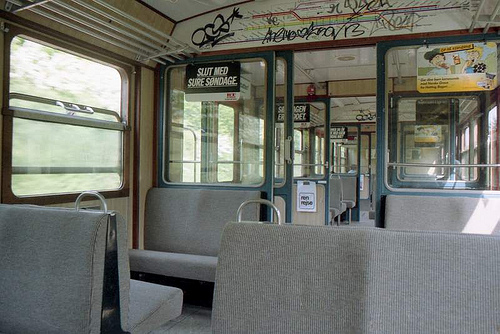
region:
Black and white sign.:
[180, 57, 241, 93]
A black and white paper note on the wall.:
[297, 179, 316, 214]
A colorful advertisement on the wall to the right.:
[414, 39, 499, 93]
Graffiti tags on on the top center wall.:
[186, 2, 429, 46]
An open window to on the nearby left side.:
[4, 35, 133, 194]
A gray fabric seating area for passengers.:
[124, 188, 260, 270]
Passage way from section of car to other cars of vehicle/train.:
[281, 44, 381, 223]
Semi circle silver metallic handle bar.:
[232, 199, 284, 230]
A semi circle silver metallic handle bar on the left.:
[71, 189, 111, 211]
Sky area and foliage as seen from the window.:
[6, 40, 127, 102]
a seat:
[149, 188, 216, 270]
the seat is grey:
[157, 190, 209, 271]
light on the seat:
[462, 201, 499, 231]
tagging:
[189, 20, 261, 50]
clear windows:
[7, 45, 136, 188]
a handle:
[244, 194, 281, 217]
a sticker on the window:
[408, 48, 498, 93]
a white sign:
[296, 183, 317, 208]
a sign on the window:
[185, 65, 245, 92]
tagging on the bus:
[262, 22, 367, 49]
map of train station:
[169, 1, 475, 48]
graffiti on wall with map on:
[183, 0, 249, 55]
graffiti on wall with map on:
[261, 22, 366, 38]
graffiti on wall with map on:
[369, 11, 414, 36]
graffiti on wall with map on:
[329, 0, 409, 18]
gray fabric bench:
[134, 182, 263, 269]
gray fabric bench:
[2, 200, 112, 332]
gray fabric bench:
[101, 205, 188, 331]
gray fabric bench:
[383, 189, 498, 231]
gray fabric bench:
[212, 212, 498, 332]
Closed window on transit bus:
[5, 106, 135, 201]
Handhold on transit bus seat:
[229, 200, 297, 228]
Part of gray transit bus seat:
[25, 245, 71, 290]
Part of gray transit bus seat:
[242, 271, 328, 310]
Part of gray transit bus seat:
[164, 207, 219, 252]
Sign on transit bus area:
[296, 178, 321, 211]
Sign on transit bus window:
[181, 61, 251, 96]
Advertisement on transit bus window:
[416, 40, 499, 90]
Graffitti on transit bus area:
[183, 10, 255, 45]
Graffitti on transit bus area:
[255, 10, 355, 39]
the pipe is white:
[118, 8, 145, 28]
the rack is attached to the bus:
[151, 29, 201, 80]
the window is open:
[18, 34, 130, 132]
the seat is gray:
[268, 253, 343, 320]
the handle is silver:
[236, 193, 282, 220]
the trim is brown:
[309, 36, 356, 51]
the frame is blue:
[373, 47, 390, 97]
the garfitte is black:
[186, 20, 247, 46]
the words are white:
[196, 65, 234, 96]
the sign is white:
[293, 172, 320, 222]